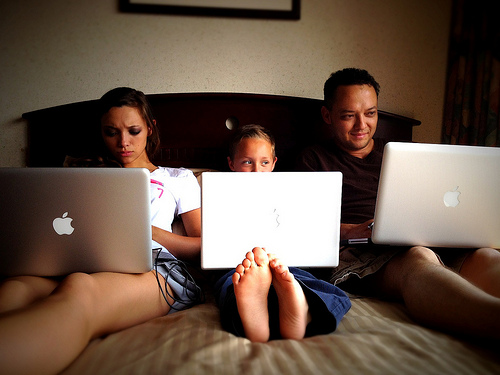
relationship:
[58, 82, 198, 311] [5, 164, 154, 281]
woman has laptop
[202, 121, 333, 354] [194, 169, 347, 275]
girl has laptop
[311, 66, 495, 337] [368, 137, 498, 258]
man has laptop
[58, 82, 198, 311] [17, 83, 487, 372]
woman on bed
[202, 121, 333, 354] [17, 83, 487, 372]
girl on bed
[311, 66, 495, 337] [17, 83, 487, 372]
man on bed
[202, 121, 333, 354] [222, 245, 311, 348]
girl has feet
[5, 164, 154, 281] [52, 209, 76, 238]
laptop has logo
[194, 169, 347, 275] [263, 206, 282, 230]
laptop has logo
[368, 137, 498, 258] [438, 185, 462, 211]
laptop has logo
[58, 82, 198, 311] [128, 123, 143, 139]
woman wearing eyeshadow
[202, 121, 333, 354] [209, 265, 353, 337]
girl has pants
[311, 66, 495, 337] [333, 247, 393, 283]
man wearing shorts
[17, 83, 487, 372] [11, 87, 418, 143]
bed has headboard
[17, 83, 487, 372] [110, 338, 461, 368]
bed has sheets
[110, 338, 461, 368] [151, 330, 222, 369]
sheets have stripes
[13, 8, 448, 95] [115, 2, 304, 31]
wall has picture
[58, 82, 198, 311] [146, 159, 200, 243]
woman has top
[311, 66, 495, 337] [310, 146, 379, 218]
man has shirt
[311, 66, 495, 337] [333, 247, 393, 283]
man has shorts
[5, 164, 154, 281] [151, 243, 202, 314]
laptop has wires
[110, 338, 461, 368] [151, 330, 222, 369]
sheets has stripes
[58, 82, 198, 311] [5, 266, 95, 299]
woman has kneecaps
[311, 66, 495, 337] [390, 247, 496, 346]
man has legs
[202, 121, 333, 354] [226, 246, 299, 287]
girl has toes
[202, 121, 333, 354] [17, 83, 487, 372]
girl relaxing on bed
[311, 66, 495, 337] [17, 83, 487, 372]
man relaxing on bed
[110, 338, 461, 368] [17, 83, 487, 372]
sheets on bed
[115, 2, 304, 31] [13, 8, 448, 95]
picture on wall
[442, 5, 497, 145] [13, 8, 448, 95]
curtain near wall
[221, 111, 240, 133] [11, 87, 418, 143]
hole in headboard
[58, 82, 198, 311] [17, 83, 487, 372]
woman sitting on bed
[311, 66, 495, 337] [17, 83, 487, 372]
man sitting on bed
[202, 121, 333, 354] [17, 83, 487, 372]
girl sitting on bed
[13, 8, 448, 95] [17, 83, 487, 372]
wall behind bed